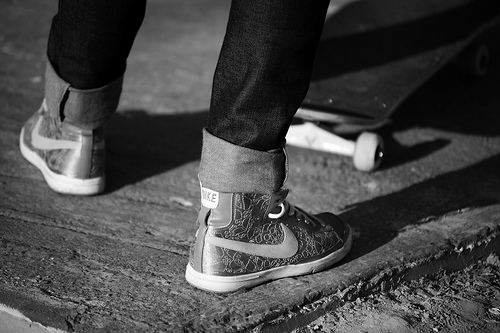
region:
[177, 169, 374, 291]
Person wearing nike shoes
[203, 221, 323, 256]
Nike logo on shoe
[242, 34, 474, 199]
Skate board with white wheels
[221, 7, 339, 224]
Person wearing black pants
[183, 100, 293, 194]
Pants legs cuffed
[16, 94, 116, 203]
Person wearing tennis shoes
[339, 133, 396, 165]
White wheels on skateboard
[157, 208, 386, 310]
Person standing ground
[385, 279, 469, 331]
Dirt on the ground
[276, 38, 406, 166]
Person with skateboard in front of them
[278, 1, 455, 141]
dark skateboard on ground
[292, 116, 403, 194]
light wheels on skateboard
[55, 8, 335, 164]
person is wearing jeans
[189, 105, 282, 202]
jeans have rolled up cuffs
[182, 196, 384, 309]
shoes have white soles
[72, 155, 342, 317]
shoes on wooden ground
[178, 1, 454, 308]
person is near skateboard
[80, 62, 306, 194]
shadow in front of person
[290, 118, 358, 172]
light axle on skateboard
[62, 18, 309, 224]
jeans on young person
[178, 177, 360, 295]
a Nike tennis shoe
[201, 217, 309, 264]
a logo on the shoe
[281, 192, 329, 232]
shoelaces on the shoe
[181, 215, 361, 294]
the sole of the shoe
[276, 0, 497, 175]
a black skateboard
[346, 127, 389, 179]
a wheel on the skateboard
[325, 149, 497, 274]
a shadow on the ground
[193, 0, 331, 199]
a leg on the person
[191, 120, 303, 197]
a cuff in the jeans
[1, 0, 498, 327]
cement on the ground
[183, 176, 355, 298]
a Nike brand high top sneaker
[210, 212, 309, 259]
the Nike swoosh on the side of a sneaker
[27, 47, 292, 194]
folded up pant legs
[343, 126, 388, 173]
the rear right wheel of a skateboard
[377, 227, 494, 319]
a crack dividing cement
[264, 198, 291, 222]
a loop in a white shoelace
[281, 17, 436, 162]
a black skateboard on the ground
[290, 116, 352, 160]
a silver metal piece between wheels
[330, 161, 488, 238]
the shadow of a person's right leg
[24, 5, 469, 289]
a person standing on a concrete beside a skateboard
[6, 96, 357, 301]
patterned nike [or fake nike] sneakers, i think maybe alligator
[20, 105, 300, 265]
big nike [or faux nike, this all seems backwards] swoosh on each shoe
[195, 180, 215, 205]
nike [or faux nike] in a rectangle @ the back of one shoe-boot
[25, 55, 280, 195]
two denim jean cuffs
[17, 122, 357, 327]
light colour trainer soles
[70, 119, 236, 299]
darker colour stripe up the back of the shoes, creating tiny stash pocket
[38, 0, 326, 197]
the bottom of the legs of a pair of straight leg jeans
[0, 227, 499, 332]
where the curb hits the road, at a junction point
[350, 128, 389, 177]
one light colour skateboard wheel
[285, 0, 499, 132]
about 1/2 a dark colour skateboard